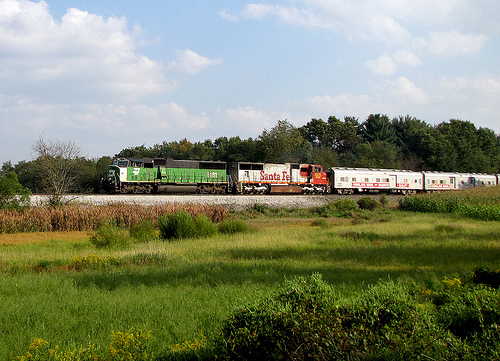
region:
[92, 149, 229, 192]
green train engine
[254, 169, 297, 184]
Sante Fe on side of train car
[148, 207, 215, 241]
big green bush in field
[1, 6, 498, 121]
white clouds in blue sky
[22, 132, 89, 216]
big bushes on side of tracks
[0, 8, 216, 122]
white clouds in sky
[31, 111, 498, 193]
green trees behind trains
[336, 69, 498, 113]
white fluffy clouds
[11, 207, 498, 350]
green grass in field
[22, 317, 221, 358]
tiny yellow flowers by bushes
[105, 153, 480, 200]
train on tracks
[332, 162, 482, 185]
white train cars on tracks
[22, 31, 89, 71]
white clouds in blue sky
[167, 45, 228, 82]
white clouds in blue sky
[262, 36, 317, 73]
white clouds in blue sky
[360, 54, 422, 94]
white clouds in blue sky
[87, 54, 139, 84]
white clouds in blue sky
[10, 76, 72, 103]
white clouds in blue sky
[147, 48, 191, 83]
white clouds in blue sky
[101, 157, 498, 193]
a long train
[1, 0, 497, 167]
white clouds in a blue sky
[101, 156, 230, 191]
a green train engine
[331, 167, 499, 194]
two white train cars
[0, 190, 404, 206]
gravels beside the train track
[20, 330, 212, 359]
yellow flower in the field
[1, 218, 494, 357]
a grassy field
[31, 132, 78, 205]
a dead tree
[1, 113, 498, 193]
trees growing on the left side of a train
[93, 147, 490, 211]
train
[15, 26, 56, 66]
white clouds in blue sky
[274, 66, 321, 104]
white clouds in blue sky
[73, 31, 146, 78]
white clouds in blue sky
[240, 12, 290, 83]
white clouds in blue sky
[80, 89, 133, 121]
white clouds in blue sky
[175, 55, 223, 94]
white clouds in blue sky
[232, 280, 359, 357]
A short green bush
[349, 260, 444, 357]
A short green bush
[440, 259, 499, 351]
A short green bush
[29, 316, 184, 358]
A short green bush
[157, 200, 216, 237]
A short green bush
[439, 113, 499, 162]
A short green tree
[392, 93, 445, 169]
A short green tree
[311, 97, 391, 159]
A short green tree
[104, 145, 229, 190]
A green train on the truck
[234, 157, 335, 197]
A white train on the truck